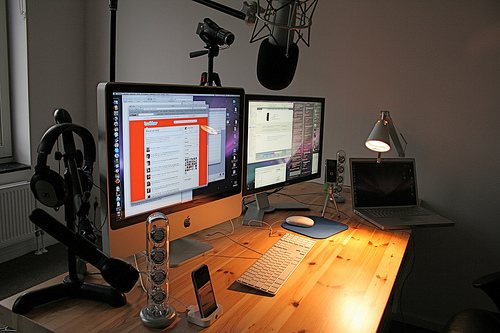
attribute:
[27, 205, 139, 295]
mic — color , black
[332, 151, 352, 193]
speaker — clear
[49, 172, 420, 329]
table — wooden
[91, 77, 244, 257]
computer — desktop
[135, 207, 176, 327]
speaker — clear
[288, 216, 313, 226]
mouse — color, white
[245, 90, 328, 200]
monitor — black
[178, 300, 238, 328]
dock — white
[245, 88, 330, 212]
monitor — large, black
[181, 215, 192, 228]
logo — apple, small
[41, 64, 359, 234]
computer — speakers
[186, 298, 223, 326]
charging dock — white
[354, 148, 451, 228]
laptop — silvery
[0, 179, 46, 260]
radiator — white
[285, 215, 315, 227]
mouse — white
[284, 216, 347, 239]
mousepad — plain, blue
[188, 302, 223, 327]
charger — white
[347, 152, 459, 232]
laptop — off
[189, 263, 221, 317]
phone — mobile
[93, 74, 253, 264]
monitor — large, silver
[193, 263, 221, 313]
phone — cell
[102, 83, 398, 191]
monitors — computer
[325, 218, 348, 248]
pad — mouse, color, blue